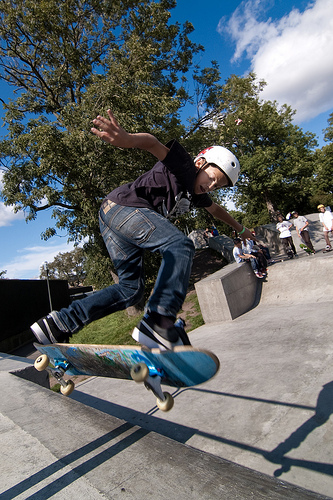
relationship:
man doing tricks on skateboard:
[35, 107, 258, 354] [31, 342, 218, 411]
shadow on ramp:
[26, 438, 116, 484] [3, 255, 332, 490]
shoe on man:
[131, 314, 190, 346] [35, 107, 258, 354]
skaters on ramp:
[234, 205, 331, 264] [264, 238, 282, 259]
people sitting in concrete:
[233, 213, 332, 268] [219, 269, 331, 436]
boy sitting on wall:
[90, 151, 266, 270] [160, 263, 316, 316]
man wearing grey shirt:
[285, 209, 315, 253] [293, 214, 307, 231]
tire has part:
[34, 354, 48, 372] [155, 399, 163, 408]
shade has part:
[202, 430, 247, 451] [215, 436, 227, 440]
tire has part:
[130, 363, 149, 384] [142, 370, 148, 378]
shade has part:
[106, 401, 199, 447] [141, 421, 148, 435]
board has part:
[29, 329, 217, 409] [167, 361, 173, 371]